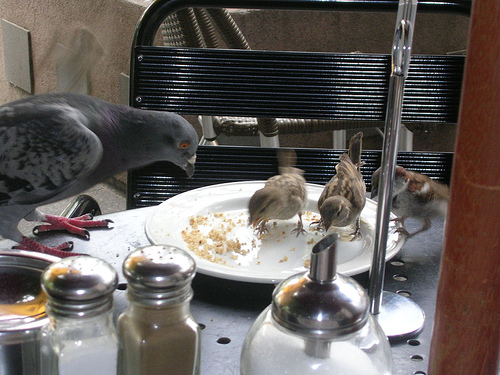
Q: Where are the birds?
A: On the plate.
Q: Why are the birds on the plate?
A: They're eating.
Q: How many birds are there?
A: Four.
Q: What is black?
A: The pigeon.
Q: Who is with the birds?
A: No one.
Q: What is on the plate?
A: Crumbs.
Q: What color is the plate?
A: White.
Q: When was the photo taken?
A: Daytime.